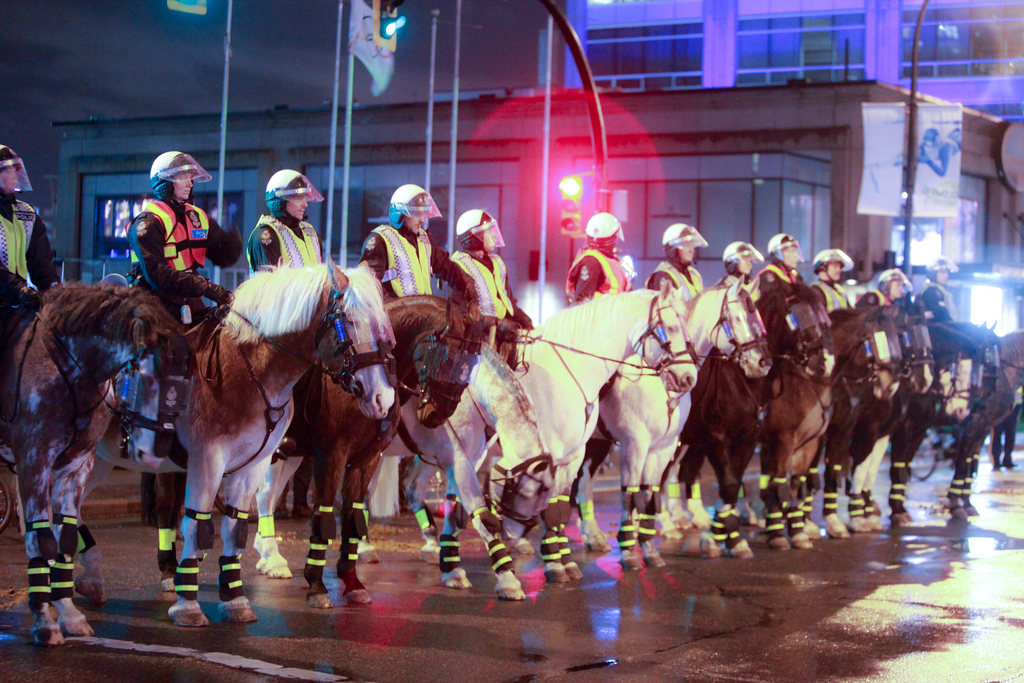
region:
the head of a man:
[134, 142, 215, 209]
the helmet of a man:
[143, 142, 201, 185]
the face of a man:
[169, 171, 207, 200]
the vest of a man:
[114, 203, 219, 261]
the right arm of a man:
[111, 215, 187, 296]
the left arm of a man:
[193, 203, 260, 264]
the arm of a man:
[213, 221, 251, 235]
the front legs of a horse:
[146, 502, 260, 633]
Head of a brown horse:
[89, 296, 235, 475]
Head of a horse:
[304, 241, 409, 425]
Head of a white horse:
[627, 270, 701, 404]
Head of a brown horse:
[770, 270, 843, 387]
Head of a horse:
[846, 295, 910, 407]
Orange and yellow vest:
[136, 191, 219, 272]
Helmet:
[146, 141, 213, 195]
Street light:
[539, 159, 594, 208]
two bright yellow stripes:
[169, 560, 204, 590]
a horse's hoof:
[169, 576, 205, 621]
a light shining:
[555, 153, 582, 199]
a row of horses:
[14, 238, 1017, 637]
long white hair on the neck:
[209, 251, 371, 344]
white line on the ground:
[0, 617, 367, 679]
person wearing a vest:
[130, 133, 245, 336]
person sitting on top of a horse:
[0, 127, 71, 346]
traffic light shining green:
[371, 11, 409, 49]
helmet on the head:
[140, 139, 218, 200]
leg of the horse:
[55, 533, 98, 585]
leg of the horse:
[146, 497, 172, 567]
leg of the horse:
[215, 541, 231, 592]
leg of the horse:
[498, 544, 519, 577]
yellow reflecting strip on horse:
[28, 516, 55, 536]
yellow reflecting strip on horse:
[28, 579, 54, 598]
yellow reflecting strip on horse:
[57, 514, 83, 530]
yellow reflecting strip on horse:
[44, 552, 80, 573]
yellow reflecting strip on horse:
[192, 506, 212, 529]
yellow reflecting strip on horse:
[174, 556, 206, 576]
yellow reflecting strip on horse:
[173, 575, 197, 596]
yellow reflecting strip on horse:
[306, 535, 330, 558]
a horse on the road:
[114, 272, 378, 558]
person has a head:
[151, 147, 203, 196]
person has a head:
[264, 169, 318, 218]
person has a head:
[383, 179, 448, 231]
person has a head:
[454, 210, 500, 253]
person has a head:
[1, 147, 33, 201]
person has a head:
[586, 208, 625, 248]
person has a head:
[662, 219, 702, 265]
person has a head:
[816, 248, 851, 280]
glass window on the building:
[585, 43, 611, 76]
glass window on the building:
[612, 39, 639, 77]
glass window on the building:
[640, 33, 670, 72]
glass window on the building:
[678, 33, 707, 66]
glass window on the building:
[732, 30, 767, 70]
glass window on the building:
[768, 27, 804, 59]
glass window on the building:
[699, 178, 748, 265]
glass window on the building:
[595, 183, 646, 260]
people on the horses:
[9, 152, 1005, 526]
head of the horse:
[616, 260, 725, 428]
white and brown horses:
[117, 255, 940, 581]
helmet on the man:
[366, 167, 466, 260]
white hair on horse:
[541, 278, 655, 345]